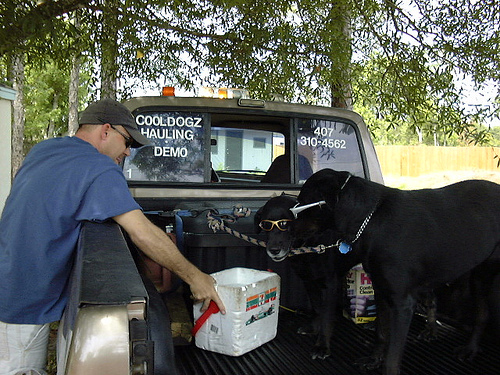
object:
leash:
[206, 210, 323, 265]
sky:
[418, 43, 496, 122]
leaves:
[215, 46, 287, 83]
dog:
[303, 167, 498, 362]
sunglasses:
[288, 199, 328, 217]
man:
[0, 106, 174, 371]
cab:
[85, 168, 270, 373]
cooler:
[192, 267, 284, 357]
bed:
[127, 196, 498, 373]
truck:
[55, 94, 499, 374]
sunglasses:
[119, 131, 136, 149]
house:
[216, 128, 277, 173]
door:
[223, 129, 250, 176]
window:
[252, 134, 269, 152]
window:
[207, 131, 219, 152]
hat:
[80, 99, 149, 144]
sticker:
[245, 284, 279, 325]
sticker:
[205, 320, 222, 337]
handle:
[189, 296, 221, 338]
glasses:
[260, 218, 289, 230]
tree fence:
[378, 58, 480, 158]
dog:
[244, 190, 324, 351]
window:
[208, 112, 300, 191]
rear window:
[210, 115, 288, 192]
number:
[298, 118, 366, 155]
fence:
[374, 130, 494, 172]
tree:
[277, 0, 487, 108]